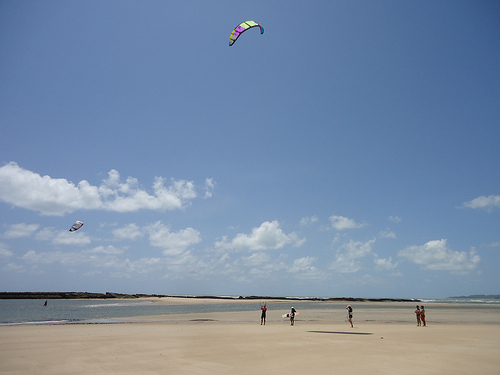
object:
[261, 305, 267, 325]
people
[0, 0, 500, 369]
outdoors